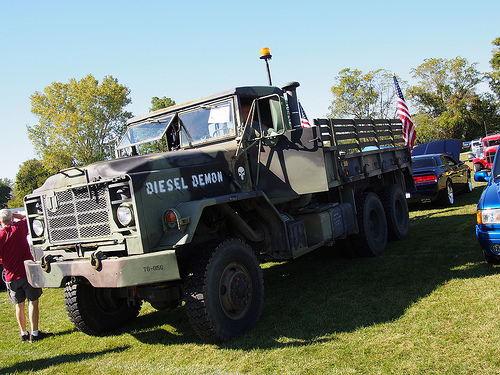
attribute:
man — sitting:
[1, 204, 45, 329]